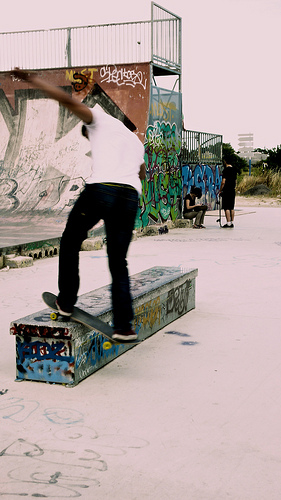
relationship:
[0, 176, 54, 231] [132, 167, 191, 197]
graffiti on wall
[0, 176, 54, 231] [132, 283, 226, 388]
graffiti on ground